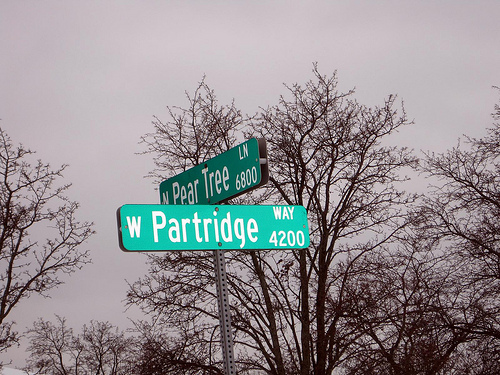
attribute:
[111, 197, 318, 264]
sign — green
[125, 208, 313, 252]
letters — white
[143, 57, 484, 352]
bare trees — tall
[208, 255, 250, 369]
pole — silver, metal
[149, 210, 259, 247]
writing — white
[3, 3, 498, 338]
sky — grey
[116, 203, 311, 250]
sign — green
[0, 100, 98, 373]
tree — leafless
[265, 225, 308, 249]
number — 4200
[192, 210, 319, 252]
sign — green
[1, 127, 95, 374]
tree — tall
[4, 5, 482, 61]
sky — gray, overcast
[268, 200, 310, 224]
word — way, white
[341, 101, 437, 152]
leaves — small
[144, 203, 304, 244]
writing — white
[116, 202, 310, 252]
background — green